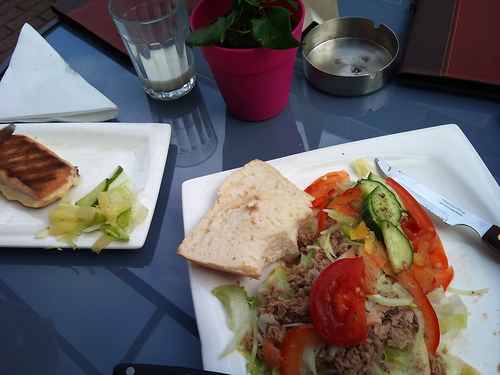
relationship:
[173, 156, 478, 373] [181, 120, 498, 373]
food on plate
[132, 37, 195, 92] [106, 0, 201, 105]
milk in glass